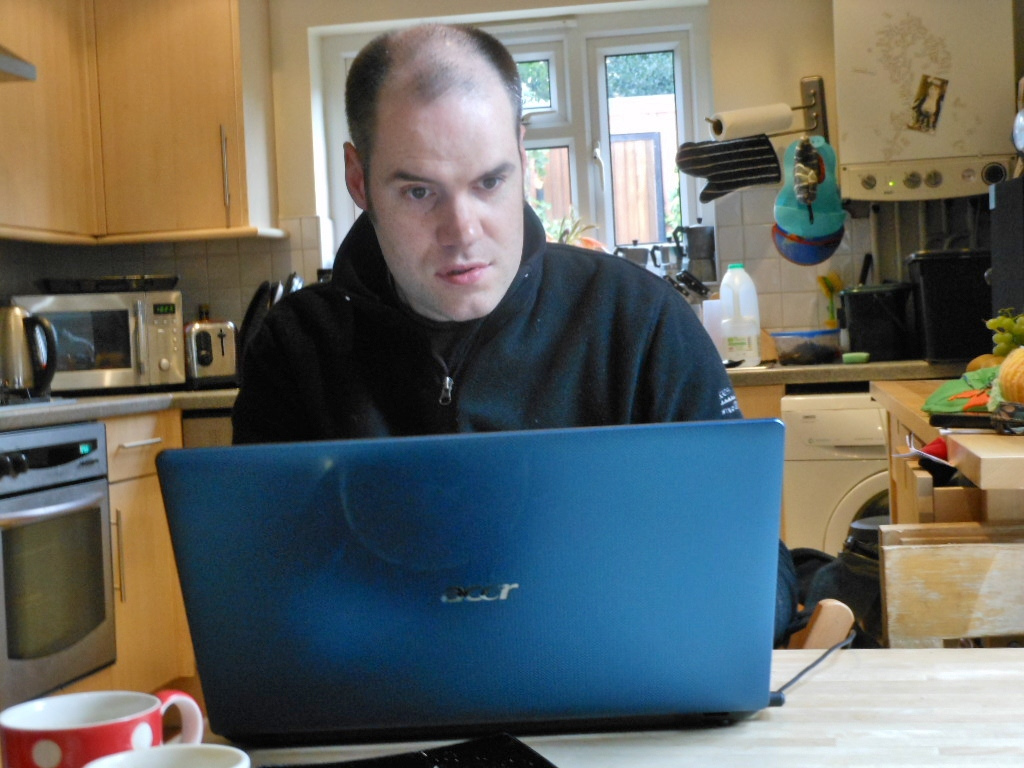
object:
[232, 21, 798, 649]
man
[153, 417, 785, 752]
computer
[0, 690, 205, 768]
mug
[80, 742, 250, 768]
mug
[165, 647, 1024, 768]
table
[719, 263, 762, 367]
bottle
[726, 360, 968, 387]
counter